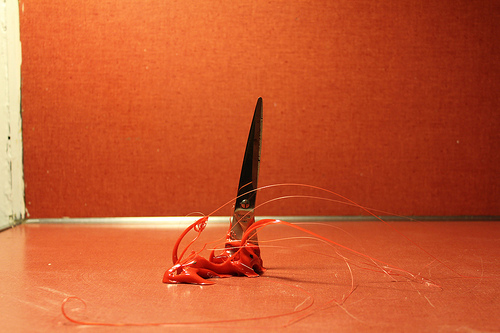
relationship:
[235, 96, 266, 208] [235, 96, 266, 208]
blades have blades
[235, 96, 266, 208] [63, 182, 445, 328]
blades have a handle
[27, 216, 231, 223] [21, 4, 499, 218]
light under door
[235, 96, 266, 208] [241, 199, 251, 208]
blades have rivet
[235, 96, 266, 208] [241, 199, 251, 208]
blades have a rivet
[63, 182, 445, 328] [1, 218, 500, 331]
handle on floor